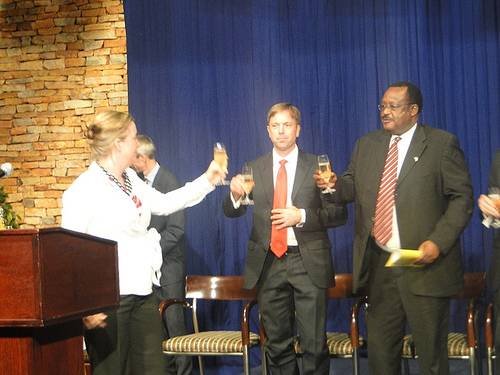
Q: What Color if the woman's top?
A: White.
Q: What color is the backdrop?
A: Blue.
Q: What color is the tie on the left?
A: Red.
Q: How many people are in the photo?
A: Four.